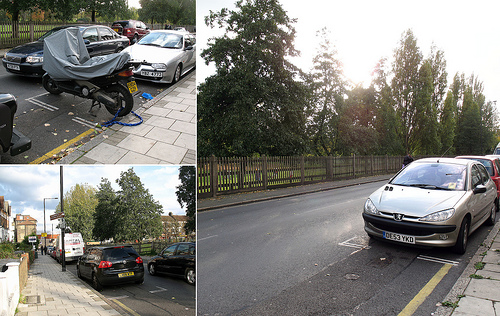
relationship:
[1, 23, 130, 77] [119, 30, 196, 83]
black car on car.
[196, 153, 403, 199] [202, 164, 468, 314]
fence surrounding street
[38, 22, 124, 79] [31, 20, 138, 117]
cover covering motorcycle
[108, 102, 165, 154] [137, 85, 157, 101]
cord attached tire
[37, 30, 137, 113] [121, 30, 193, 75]
motorcycle parked car.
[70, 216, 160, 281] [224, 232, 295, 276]
cars parked street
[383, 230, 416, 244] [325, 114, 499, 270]
license plate hanging car.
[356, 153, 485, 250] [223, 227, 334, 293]
car parked road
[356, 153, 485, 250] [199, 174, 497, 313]
car are parked at road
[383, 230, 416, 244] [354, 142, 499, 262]
license plate on car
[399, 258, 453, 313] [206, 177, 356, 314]
line on road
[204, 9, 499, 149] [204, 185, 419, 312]
trees on side of road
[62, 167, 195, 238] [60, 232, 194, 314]
trees on side of road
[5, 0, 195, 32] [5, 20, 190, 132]
trees on side of road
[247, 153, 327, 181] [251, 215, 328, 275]
fence on side of road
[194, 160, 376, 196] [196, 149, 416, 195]
grass on side of fence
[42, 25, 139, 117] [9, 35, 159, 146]
motorcycle parked on road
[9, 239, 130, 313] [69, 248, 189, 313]
sidewalk next to road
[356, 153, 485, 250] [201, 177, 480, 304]
car parked on street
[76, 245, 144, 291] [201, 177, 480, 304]
cars parked on street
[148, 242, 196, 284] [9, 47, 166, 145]
parkedcars parked on street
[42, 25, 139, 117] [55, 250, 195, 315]
motorcycle parked on street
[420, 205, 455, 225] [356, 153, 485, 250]
headlight in front of car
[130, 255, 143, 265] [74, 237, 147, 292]
taillight on vehicle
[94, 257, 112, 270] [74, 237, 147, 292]
taillight on vehicle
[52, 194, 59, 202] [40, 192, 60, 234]
light on pole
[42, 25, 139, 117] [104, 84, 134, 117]
motorcycle has tire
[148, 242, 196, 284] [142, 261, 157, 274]
parkedcars has wheel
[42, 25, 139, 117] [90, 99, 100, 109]
motorcycle has kickstand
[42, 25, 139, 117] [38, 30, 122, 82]
motorcycle has cover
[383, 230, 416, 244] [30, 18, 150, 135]
license plate on motorcycle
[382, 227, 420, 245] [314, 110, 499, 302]
license plate on car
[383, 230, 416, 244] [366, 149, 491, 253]
license plate on vehicle